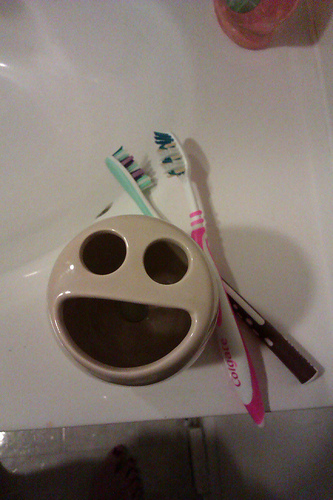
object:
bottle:
[212, 0, 303, 52]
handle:
[184, 177, 266, 429]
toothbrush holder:
[0, 0, 333, 430]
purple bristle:
[129, 166, 146, 182]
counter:
[0, 0, 332, 432]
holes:
[78, 225, 129, 277]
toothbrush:
[151, 120, 267, 429]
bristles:
[152, 128, 188, 180]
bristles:
[111, 143, 157, 193]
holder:
[47, 212, 220, 387]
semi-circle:
[54, 293, 194, 373]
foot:
[85, 442, 140, 499]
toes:
[105, 442, 127, 474]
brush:
[102, 138, 323, 385]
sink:
[0, 0, 192, 280]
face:
[47, 213, 214, 377]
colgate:
[218, 335, 242, 387]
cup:
[45, 212, 221, 388]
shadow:
[182, 222, 317, 365]